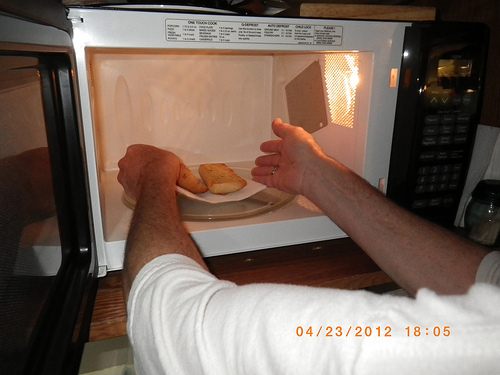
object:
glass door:
[0, 51, 102, 357]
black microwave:
[0, 5, 483, 375]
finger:
[260, 140, 283, 153]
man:
[117, 117, 499, 374]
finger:
[254, 154, 283, 167]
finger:
[272, 118, 303, 140]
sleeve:
[126, 252, 500, 374]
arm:
[116, 144, 415, 375]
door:
[0, 16, 107, 374]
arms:
[251, 118, 499, 301]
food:
[178, 163, 247, 194]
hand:
[251, 117, 324, 195]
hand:
[117, 144, 181, 202]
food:
[139, 134, 292, 213]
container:
[464, 179, 499, 245]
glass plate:
[123, 167, 298, 220]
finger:
[251, 111, 302, 189]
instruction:
[164, 19, 343, 46]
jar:
[463, 179, 498, 245]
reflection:
[1, 148, 56, 252]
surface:
[0, 28, 93, 368]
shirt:
[126, 251, 500, 374]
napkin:
[175, 179, 268, 204]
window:
[0, 65, 65, 374]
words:
[167, 20, 341, 44]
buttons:
[413, 87, 472, 208]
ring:
[272, 166, 279, 175]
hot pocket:
[198, 163, 247, 195]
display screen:
[437, 59, 472, 78]